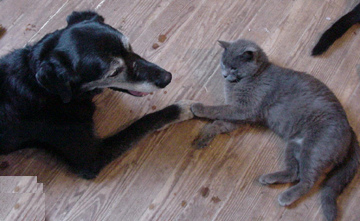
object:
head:
[216, 38, 263, 82]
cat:
[187, 38, 359, 221]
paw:
[187, 101, 202, 117]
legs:
[206, 94, 267, 125]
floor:
[0, 0, 359, 221]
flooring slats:
[339, 192, 360, 221]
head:
[56, 19, 172, 98]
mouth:
[111, 86, 162, 98]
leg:
[48, 101, 178, 179]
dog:
[0, 11, 198, 178]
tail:
[317, 138, 359, 221]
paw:
[168, 98, 192, 122]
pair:
[172, 99, 206, 121]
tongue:
[129, 90, 148, 97]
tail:
[306, 4, 360, 57]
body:
[189, 62, 352, 205]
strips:
[144, 148, 195, 221]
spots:
[193, 185, 210, 196]